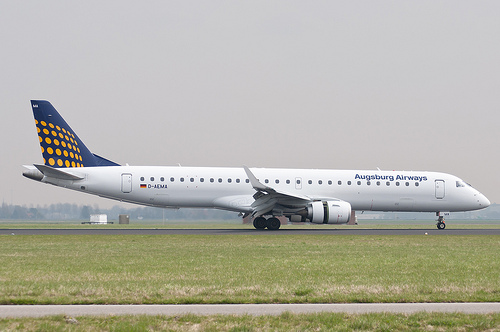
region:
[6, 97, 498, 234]
this is a plane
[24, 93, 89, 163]
this is the tail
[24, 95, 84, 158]
the tail is sharp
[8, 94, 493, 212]
the plane is big in size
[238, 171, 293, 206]
this is the wing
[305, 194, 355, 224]
this is a propeller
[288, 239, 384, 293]
this is the grass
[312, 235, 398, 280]
the grass is green in color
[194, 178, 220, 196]
the plane is white in color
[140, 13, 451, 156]
the sky is grey in color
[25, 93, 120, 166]
The blue tail of the plane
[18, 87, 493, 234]
The plane on the runway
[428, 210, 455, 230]
The front wheels of the plane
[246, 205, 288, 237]
The back wheels of the plane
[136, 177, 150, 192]
The flag on the plane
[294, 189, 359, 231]
The right engine of the plane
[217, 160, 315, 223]
The right wing of the plane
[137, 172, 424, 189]
The windows on the side of the plane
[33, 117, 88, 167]
The yellow dots on the plane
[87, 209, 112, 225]
The white structure on the grass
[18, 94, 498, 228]
commercial airline on runway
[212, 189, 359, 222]
wing and engine of commercial airline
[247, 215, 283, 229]
wheels on wing of commercial airline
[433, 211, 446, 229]
front wheel of commercial airline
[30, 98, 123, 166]
tail wing of commercial airline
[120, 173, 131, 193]
backdoor of commercial airline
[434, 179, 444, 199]
front door of commercial airline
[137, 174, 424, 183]
windows of commercial airline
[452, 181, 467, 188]
cockpit of commercial airline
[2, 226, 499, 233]
runway of airport where commercial airline sits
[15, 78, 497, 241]
A passenger airplane on the runway.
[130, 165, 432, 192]
Passenger windows on the side of the airplane.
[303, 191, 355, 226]
Engine on right side of the airplane.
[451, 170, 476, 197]
Windows on the cockpit.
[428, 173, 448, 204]
Door at the front of the airplane.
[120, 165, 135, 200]
Door at the back of the airplane.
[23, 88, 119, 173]
Tail section of an airplane.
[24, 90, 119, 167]
The tail section is blue and yellow.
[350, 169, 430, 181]
The name of the airline Augsburg Airways.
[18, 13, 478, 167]
The sky looks hazy.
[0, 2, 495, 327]
Daytime at the airport.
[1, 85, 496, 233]
The plane is on the tarmac.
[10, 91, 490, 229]
The plane is white, blue, and yellow.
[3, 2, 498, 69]
The sky is overcast.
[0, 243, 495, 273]
The grass is green.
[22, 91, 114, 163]
The rudder on the airplane is blue with yellow dots.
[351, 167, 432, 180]
The blue text on the plane says Augsburg Airways.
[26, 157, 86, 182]
A small wing on the plane.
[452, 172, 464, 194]
Window on the cockpit.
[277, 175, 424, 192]
Passenger windows on the airplane.